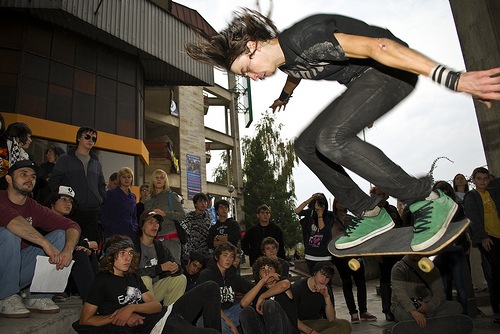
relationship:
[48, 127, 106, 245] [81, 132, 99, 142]
boy wearing glasses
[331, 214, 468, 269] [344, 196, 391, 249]
skate wearing green shoe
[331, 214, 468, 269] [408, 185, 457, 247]
skate wearing green shoe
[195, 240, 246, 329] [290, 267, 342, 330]
boy watching boy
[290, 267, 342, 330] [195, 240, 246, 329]
boy watching boy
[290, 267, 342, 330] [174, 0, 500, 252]
boy watching man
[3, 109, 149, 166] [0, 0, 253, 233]
orange trim of building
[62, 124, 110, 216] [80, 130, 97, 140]
boy in glasses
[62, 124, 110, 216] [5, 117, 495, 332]
boy in crowd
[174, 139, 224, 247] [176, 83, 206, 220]
poster on wall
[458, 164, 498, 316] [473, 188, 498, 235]
kid in shirt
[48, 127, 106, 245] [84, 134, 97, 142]
boy wearing glasses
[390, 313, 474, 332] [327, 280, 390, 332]
skateboard on ground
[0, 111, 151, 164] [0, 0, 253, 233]
bar on building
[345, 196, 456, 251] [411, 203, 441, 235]
shoes with laces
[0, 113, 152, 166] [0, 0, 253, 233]
accent on building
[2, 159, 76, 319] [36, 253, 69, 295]
man holding paper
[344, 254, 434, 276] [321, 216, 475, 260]
wheels on skateboard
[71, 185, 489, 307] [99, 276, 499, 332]
boys sitting on ground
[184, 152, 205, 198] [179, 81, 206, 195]
advertisement on wall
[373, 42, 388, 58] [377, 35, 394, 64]
scab on elbow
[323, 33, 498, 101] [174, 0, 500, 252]
arm of a man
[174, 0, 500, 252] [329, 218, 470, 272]
man riding on skateboard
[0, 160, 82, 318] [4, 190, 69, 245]
man wearing shirt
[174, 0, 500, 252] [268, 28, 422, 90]
man wearing shirt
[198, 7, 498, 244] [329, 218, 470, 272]
man riding skateboard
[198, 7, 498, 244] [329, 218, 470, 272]
man on skateboard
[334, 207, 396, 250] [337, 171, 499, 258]
green shoe on feet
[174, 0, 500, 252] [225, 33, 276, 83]
man has head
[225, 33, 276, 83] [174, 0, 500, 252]
head of man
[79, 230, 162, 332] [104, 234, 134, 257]
person wearing hat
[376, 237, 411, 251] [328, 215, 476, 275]
grip tape on board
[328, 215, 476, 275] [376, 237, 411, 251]
board has grip tape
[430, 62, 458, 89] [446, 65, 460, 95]
bracelets on wrist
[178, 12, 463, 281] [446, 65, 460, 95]
man has wrist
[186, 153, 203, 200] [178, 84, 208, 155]
poster attached to wall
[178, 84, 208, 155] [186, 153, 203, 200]
wall has poster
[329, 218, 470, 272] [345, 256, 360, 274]
skateboard has wheel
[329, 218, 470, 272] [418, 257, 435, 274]
skateboard has wheel